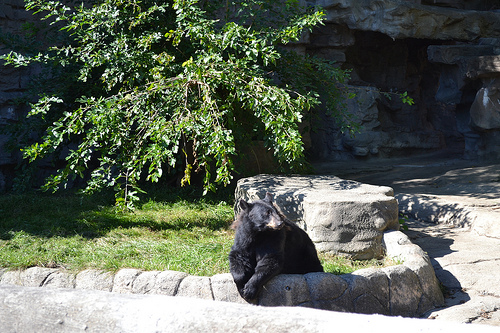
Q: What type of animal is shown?
A: Bear.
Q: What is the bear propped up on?
A: Rocks.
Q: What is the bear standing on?
A: Grass.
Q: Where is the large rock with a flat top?
A: Behind the bear.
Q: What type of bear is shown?
A: Black bear.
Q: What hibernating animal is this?
A: Bear.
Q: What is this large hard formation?
A: Rock.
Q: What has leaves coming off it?
A: Branches.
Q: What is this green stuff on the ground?
A: Grass.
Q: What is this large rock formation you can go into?
A: Cave.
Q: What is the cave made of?
A: Rocks.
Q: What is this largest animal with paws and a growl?
A: Bear.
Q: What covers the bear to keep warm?
A: Fur.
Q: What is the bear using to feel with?
A: Hands.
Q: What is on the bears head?
A: Ears.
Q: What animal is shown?
A: Bear.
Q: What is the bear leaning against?
A: A rock barrier.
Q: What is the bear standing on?
A: Grass.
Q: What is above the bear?
A: Branches.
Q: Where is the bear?
A: In a zoo.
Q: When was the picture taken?
A: During the day time.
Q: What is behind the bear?
A: A stone wall.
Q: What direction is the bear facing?
A: To the right.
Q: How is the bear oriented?
A: Standing on the hind legs.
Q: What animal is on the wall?
A: Bear.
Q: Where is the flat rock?
A: Behind bear.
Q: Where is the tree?
A: Behind the bear.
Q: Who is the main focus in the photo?
A: Bear.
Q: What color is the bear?
A: Black.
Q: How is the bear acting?
A: Relaxed.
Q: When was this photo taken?
A: Daytime.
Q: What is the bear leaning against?
A: Rock wall.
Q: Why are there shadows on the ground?
A: Sun is shining.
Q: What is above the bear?
A: Tree branches.